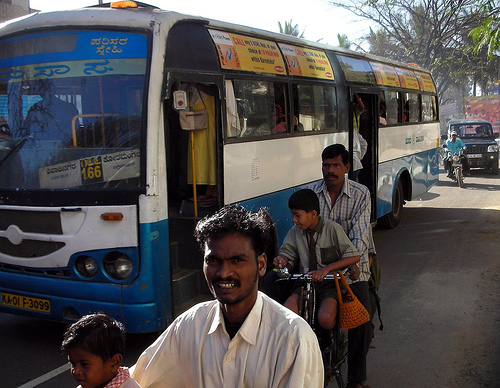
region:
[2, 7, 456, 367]
several Indian people outside a large bus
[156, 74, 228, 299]
open door at the front of the bus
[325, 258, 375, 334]
an orange bag the young person has attached to a bike handle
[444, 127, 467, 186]
a man with a blue shirt riding a bicycle behind the bus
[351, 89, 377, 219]
open door in the middle of the bus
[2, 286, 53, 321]
a yellow license plate with black lettering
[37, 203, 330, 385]
a smiling man with his young child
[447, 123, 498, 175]
a black small suv type vehicle behind the bus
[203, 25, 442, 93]
yellow advertisements across the top of the bus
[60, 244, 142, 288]
two round front headlights on the bus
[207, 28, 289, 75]
Advertisement on side of passenger bus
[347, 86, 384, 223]
Rear access door for passenger bus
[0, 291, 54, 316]
License plate for passenger bus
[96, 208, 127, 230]
Turn signal on passenger bus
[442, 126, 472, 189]
Man riding a scooter in the background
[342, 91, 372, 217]
Passenger loading or unloading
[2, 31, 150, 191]
Windshield on a passenger bus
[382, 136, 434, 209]
Reflection on the side of a passenger bus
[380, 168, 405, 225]
Rear wheel of a passenger bus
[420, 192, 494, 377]
Street made out of concrete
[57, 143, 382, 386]
the four people next to the bus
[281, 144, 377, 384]
the man and child on the bike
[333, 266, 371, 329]
the orange bag hanging on the bike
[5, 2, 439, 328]
the blue, white, and black bus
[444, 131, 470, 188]
the person on the bike behind the bus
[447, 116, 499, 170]
the car behind the bus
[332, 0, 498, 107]
the trees in the back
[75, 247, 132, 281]
the light in front of the bus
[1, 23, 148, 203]
the windshield of the bus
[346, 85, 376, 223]
the back door on the bus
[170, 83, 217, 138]
brown hand bag on shoulder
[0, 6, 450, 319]
large bus for public transportation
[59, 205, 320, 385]
man in white shirt with young child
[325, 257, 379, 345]
woven purse hanging from handle bars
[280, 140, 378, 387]
man and child riding on bike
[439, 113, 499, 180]
motorcycle in front of jeep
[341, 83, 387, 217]
person standing in door way of bus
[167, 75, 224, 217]
partial view of woman in yellow dress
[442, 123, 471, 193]
man in teal shirt riding motorcycle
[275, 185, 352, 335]
young boy with dress shirt and tie on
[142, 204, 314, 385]
man in white shirt looking at camera